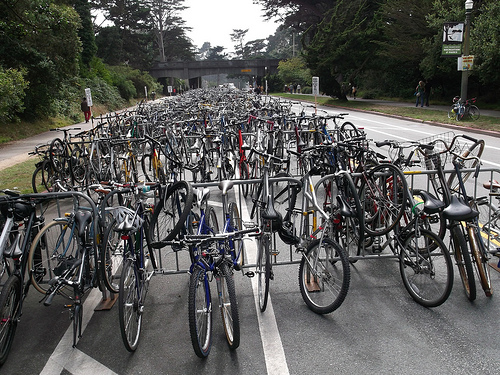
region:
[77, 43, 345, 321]
many different bikes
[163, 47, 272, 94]
bridge behind the bikes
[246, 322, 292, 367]
white line under the bikes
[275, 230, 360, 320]
tire on the bike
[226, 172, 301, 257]
rack for the bikes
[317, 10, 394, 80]
trees next to the road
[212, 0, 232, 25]
sky above the land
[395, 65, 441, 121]
people walking on sidewalk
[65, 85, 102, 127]
person walking on the cement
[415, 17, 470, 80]
sign on the pole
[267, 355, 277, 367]
the line is white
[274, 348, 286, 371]
the line is white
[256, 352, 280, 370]
the line is white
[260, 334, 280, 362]
the line is white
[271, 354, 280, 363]
the line is white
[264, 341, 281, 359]
the line is white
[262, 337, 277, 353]
the line is white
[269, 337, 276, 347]
the line is white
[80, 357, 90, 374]
the line is white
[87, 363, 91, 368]
the line is white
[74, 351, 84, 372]
the line is white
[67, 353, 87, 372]
the line is white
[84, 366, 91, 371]
the line is white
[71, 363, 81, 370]
the line is white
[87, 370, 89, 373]
the line is white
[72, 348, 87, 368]
the line is white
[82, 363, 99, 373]
the line is white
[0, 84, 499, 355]
rows of bicycles on racks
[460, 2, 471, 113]
light post on side of road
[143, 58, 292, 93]
concrete bridge over bike path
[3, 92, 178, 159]
sidewalk on the left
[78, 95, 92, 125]
person in red pants walking on sidewalk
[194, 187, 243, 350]
two blue bikes on front row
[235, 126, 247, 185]
bright red bike on the second row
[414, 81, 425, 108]
woman with a purse walking away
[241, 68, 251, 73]
yellow sign on the bridge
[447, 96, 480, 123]
two bikes leaning against the lamp post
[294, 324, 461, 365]
this is the road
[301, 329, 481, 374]
the road is clean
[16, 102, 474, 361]
these are several bicycles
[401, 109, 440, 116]
this is the grass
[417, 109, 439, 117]
the grass is green in color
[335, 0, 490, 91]
these are some trees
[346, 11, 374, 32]
the leaves are green in color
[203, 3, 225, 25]
this is the sky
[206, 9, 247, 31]
the sky is clear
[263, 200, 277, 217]
the seat is black in color